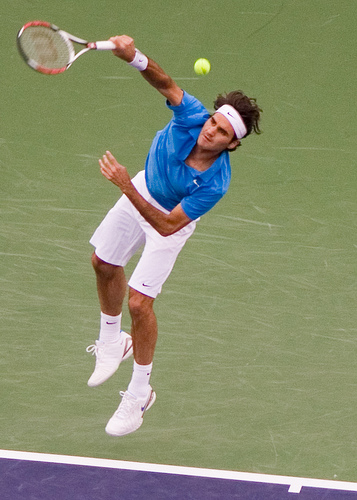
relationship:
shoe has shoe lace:
[86, 329, 133, 385] [84, 343, 101, 357]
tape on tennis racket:
[95, 36, 117, 48] [15, 19, 120, 73]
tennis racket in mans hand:
[15, 19, 120, 73] [106, 30, 135, 64]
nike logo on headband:
[225, 110, 234, 118] [214, 104, 249, 139]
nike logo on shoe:
[137, 394, 151, 414] [86, 329, 133, 387]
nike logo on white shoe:
[137, 394, 151, 414] [86, 326, 137, 397]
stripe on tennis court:
[0, 449, 357, 494] [0, 0, 357, 498]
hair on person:
[220, 86, 282, 141] [87, 31, 258, 436]